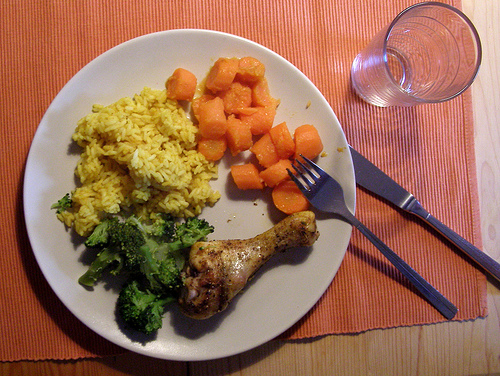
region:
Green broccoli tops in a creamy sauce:
[85, 206, 196, 317]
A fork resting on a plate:
[285, 145, 425, 287]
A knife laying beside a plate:
[335, 135, 470, 240]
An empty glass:
[346, 15, 496, 121]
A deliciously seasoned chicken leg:
[171, 195, 316, 325]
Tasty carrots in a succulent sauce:
[170, 55, 320, 196]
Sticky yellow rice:
[66, 70, 197, 228]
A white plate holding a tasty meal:
[85, 122, 353, 366]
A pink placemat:
[263, 145, 493, 333]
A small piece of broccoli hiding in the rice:
[51, 188, 91, 214]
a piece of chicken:
[181, 212, 321, 319]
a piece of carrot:
[228, 161, 260, 191]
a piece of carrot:
[273, 182, 313, 213]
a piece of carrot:
[263, 160, 294, 184]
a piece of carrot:
[293, 121, 318, 160]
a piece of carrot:
[252, 132, 279, 163]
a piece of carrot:
[269, 121, 296, 156]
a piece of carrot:
[198, 102, 225, 127]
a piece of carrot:
[171, 66, 194, 96]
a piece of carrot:
[208, 60, 233, 92]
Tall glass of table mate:
[355, 5, 487, 110]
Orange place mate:
[0, 0, 485, 346]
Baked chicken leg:
[160, 210, 325, 335]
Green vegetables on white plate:
[65, 197, 211, 342]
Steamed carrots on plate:
[160, 40, 325, 215]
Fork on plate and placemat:
[271, 141, 461, 322]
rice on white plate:
[67, 83, 232, 210]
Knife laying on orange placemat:
[330, 120, 480, 310]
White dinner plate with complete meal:
[7, 10, 384, 372]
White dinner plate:
[11, 20, 351, 371]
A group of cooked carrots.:
[218, 49, 289, 211]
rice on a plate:
[58, 100, 177, 211]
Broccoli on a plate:
[111, 216, 215, 340]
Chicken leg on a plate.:
[182, 197, 309, 337]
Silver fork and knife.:
[301, 151, 496, 374]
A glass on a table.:
[340, 3, 478, 141]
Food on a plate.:
[88, 52, 314, 344]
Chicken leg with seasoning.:
[174, 200, 324, 334]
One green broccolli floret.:
[110, 282, 177, 350]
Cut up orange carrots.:
[166, 44, 316, 216]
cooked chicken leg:
[186, 212, 318, 319]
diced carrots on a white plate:
[196, 72, 308, 157]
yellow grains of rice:
[74, 100, 198, 202]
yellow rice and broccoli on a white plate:
[78, 104, 187, 320]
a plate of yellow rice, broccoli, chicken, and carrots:
[66, 45, 295, 345]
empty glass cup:
[352, 0, 487, 119]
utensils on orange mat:
[353, 143, 498, 323]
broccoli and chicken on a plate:
[102, 212, 314, 337]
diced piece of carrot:
[228, 164, 260, 187]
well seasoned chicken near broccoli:
[160, 216, 324, 316]